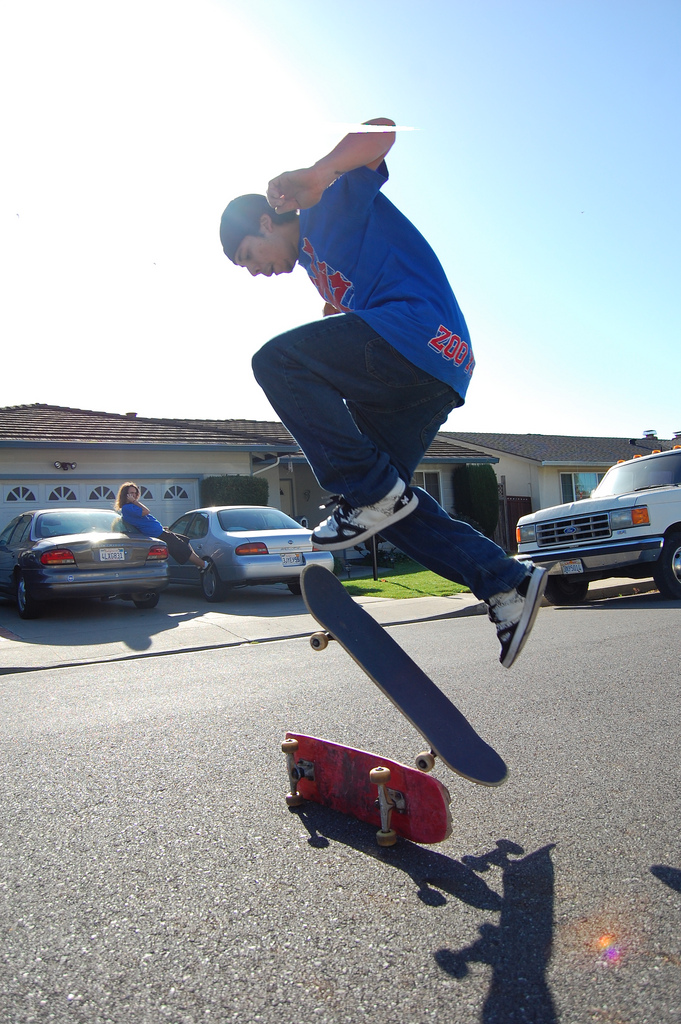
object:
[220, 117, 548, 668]
boy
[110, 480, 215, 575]
girl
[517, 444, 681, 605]
truck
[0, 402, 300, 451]
roof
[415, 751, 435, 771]
wheel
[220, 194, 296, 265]
hat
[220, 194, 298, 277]
head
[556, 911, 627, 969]
spray paiint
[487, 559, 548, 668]
shoe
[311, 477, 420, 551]
shoe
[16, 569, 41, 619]
wheel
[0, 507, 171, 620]
vehicle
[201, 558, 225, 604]
wheel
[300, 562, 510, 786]
skateboard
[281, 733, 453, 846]
skateboard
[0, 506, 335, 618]
cars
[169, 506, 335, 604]
car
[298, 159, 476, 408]
guy's shirt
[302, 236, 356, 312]
writing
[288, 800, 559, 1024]
shadow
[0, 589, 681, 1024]
road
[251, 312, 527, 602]
jeans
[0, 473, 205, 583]
garage door